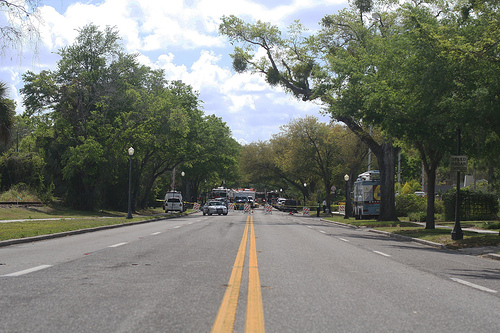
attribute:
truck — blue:
[351, 168, 382, 219]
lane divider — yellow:
[240, 222, 263, 317]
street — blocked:
[197, 221, 230, 247]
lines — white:
[319, 226, 393, 273]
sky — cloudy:
[184, 31, 219, 67]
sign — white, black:
[451, 152, 470, 174]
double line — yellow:
[230, 217, 263, 304]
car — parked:
[284, 198, 298, 217]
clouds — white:
[163, 19, 190, 43]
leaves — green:
[422, 59, 439, 74]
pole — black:
[123, 163, 140, 214]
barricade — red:
[260, 204, 278, 220]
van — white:
[161, 189, 182, 215]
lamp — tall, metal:
[302, 187, 311, 205]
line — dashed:
[15, 220, 197, 291]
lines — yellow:
[226, 226, 271, 285]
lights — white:
[120, 139, 154, 164]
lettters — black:
[453, 157, 472, 163]